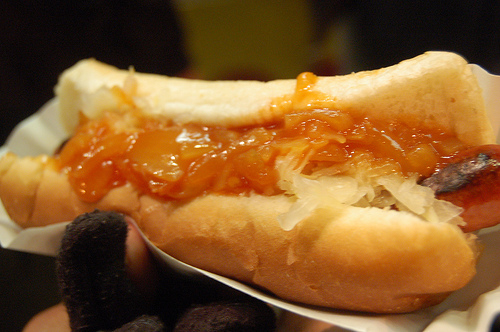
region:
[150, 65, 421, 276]
person is holding hot dog in hand.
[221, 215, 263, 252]
bread is brown color.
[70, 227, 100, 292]
gloves is black color.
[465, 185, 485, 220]
hot dog is brown color.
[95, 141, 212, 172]
sauce is orange color.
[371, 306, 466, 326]
paper is white color.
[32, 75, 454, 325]
hot dog is in paper.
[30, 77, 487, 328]
one hot dog is seen.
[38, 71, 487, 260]
hot dog is between the bread.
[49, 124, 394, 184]
orange sauce is kept over the hot dog.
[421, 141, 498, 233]
a pink hot dog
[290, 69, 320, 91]
orange sauce on the bun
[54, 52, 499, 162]
half of a hot dog bun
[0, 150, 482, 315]
half of a hot dog bun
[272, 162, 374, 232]
white pieces of sauerkraut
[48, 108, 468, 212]
orange sauce on the sauerkraut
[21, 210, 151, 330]
a person's finger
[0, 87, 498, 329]
a white piece of paper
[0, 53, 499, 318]
a hot dog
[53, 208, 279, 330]
a black glove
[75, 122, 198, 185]
This is buffalo sauce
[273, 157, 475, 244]
This is saurkraut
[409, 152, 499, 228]
This is a hot dog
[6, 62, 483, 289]
This is a hot dog bun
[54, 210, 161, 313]
This is the color black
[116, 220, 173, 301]
This is a hand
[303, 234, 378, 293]
This is brown bread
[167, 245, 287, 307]
This is white paper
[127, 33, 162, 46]
This is the color brown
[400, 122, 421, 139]
This is the color orange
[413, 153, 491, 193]
There is a burnt spot on the hot dog.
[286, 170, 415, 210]
There is sauerkraut on the hot dog.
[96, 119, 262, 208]
There is sauce on the hot dog.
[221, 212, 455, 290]
The hot dog is o a bun.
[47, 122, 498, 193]
A hot dog on the bun.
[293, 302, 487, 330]
The wrapper the hot dog is in is white.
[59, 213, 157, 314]
Part of the glove is ripped.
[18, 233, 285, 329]
Someone wearing gloves is holding the hot dog.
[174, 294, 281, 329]
The gloves are black.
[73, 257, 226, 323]
The gloves are fuzzy.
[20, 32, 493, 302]
toppings in middle of white bread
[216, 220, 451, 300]
brown crust on outside of bread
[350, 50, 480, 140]
inside of hot dog bun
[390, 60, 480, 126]
air bubbles inside baked bread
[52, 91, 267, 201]
gooey cooked onions in sauce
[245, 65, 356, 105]
sauce dripping over side of bread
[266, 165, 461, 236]
translucent shreds of sauerkraut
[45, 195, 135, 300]
gloved finger on side of bread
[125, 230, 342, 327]
paper underneath hot dog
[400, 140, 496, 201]
burn mark on hot dog